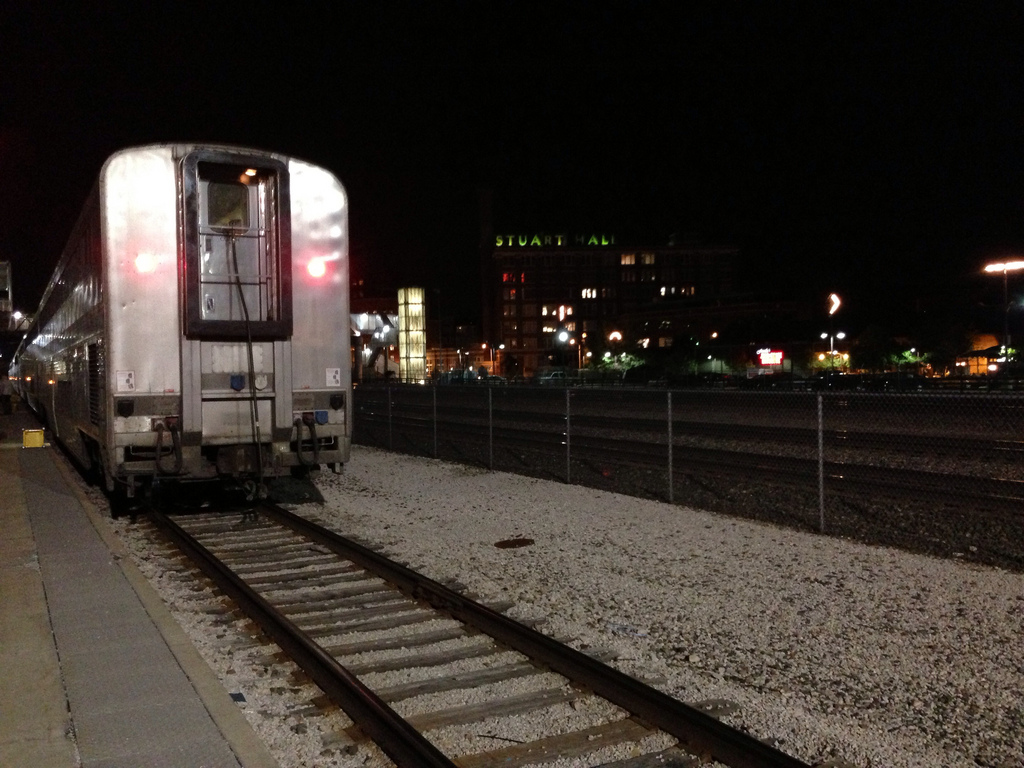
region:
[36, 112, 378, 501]
the back of a train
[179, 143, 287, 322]
the window of a train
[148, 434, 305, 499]
the connecting part of a train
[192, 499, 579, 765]
the tracks of a train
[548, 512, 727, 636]
a bunch of grey gravel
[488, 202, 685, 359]
a large building that has lights on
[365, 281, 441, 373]
a tall tower that is lit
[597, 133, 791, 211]
a pitch black night sky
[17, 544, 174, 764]
the platform of a train station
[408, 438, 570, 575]
A person eating a orange.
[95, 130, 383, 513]
Train on train track.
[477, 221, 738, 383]
A hotel adjacent to train station.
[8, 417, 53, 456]
A stool to help people claim on trains.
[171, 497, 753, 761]
Active train track.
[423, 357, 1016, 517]
Fences separating train tracks.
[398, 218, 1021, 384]
Commercial district near the train station.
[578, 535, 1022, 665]
Gravels spread next to the train track.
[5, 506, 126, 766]
Concrete floor for train passengers.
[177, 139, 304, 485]
Train's back door.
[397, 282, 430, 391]
Decorative light next to the train station.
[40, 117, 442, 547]
back of the train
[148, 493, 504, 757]
track under the train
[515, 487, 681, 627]
rocks next to the train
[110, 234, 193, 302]
red light on train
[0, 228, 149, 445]
side of the train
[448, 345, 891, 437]
top of the fence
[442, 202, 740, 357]
building in the distance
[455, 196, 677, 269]
words on top of building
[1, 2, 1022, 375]
A black sky.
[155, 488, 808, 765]
A brown train track.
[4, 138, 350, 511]
A silver train on a track.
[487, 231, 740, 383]
A large building with green letters on the top.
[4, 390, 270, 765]
A concrete walkway beside a train track.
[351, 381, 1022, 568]
A chain link fence beside a train.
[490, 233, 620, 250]
Green words STUART HALL on a building top.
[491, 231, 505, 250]
Large green S on a building.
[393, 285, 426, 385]
A lit up rounded tower.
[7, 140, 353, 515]
A silver train.